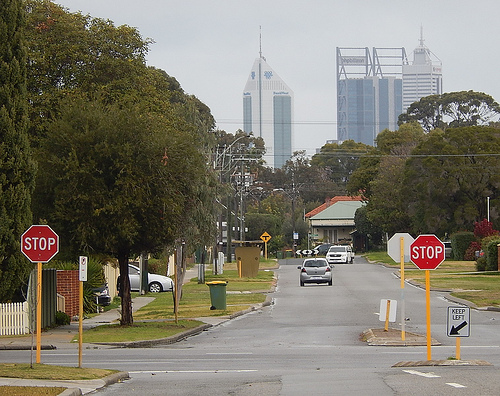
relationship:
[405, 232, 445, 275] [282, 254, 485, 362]
stop sign on street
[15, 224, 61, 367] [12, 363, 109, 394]
stop sign on sidewalk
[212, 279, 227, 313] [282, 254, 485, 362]
trash can near street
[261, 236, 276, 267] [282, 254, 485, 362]
sign near street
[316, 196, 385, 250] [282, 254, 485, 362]
house near street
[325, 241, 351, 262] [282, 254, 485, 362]
van on street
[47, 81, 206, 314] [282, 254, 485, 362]
tree near street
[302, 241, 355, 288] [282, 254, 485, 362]
cars are in street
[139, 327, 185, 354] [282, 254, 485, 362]
curb near street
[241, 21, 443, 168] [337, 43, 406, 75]
buildings have roofs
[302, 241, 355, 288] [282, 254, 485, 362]
cars driving on street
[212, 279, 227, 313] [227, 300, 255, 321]
trash can near curb